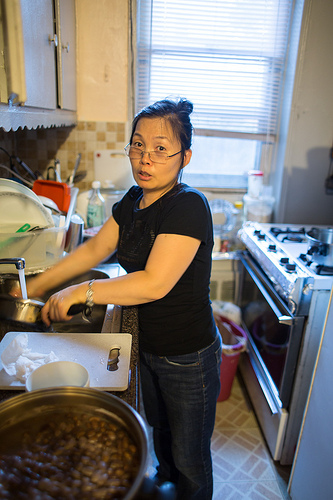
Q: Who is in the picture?
A: A lady.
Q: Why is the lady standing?
A: Washing.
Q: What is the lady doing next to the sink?
A: Washing a pan.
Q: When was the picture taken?
A: Daytime.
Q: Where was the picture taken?
A: In the kitchen.